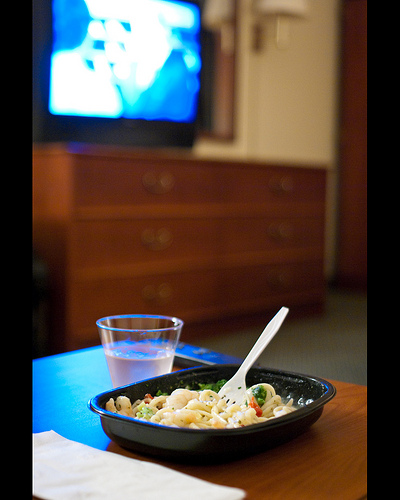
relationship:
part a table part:
[28, 327, 390, 498] [179, 350, 253, 372]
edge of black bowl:
[253, 359, 338, 392] [89, 363, 338, 471]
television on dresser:
[40, 4, 222, 133] [32, 148, 328, 351]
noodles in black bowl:
[174, 394, 264, 428] [89, 363, 338, 471]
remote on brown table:
[149, 330, 261, 371] [248, 377, 367, 499]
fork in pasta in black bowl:
[212, 305, 302, 395] [89, 363, 338, 471]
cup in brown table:
[90, 305, 183, 384] [248, 377, 367, 499]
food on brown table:
[92, 358, 345, 448] [248, 377, 367, 499]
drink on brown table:
[96, 313, 184, 389] [248, 377, 367, 499]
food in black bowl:
[106, 385, 302, 427] [89, 363, 338, 471]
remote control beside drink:
[128, 330, 246, 371] [96, 313, 184, 389]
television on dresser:
[49, 1, 196, 124] [32, 148, 328, 351]